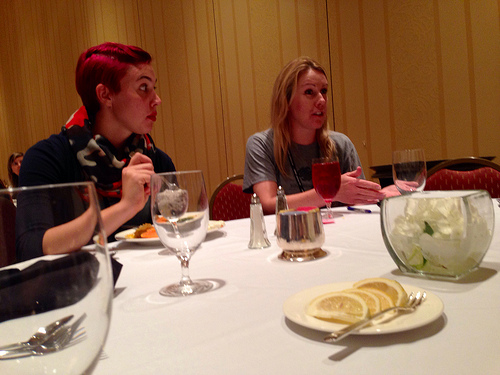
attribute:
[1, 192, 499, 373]
table cloth — white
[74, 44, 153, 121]
hair — red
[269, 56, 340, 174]
girl — blonde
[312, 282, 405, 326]
lemon slices — sliced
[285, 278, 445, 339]
plate — round, white, small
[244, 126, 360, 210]
shirt — grey, gray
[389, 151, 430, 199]
glass — empty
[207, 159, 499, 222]
chairs — red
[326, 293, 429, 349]
forks — silver, small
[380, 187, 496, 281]
bowl — glass, small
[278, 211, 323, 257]
container — silver, small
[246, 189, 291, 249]
shakers — salt, pepper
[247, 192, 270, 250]
salt shaker — slim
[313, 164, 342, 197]
liquid — red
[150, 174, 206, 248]
glass — clear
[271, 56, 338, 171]
hair — long, blond, brown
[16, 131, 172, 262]
hoodie — black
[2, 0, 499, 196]
wall — light brown